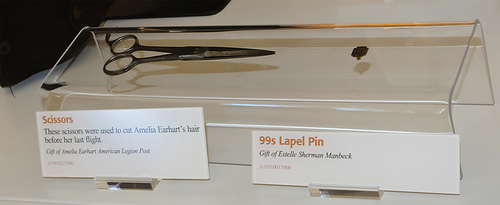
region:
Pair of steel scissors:
[90, 25, 306, 93]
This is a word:
[39, 112, 79, 127]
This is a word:
[37, 125, 61, 137]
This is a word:
[58, 124, 85, 136]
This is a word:
[81, 124, 102, 136]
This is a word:
[277, 132, 307, 147]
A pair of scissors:
[105, 33, 269, 78]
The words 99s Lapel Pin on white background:
[254, 130, 334, 152]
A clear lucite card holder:
[89, 171, 168, 190]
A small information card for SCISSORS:
[39, 103, 207, 180]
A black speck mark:
[342, 38, 376, 69]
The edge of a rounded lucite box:
[414, 13, 495, 173]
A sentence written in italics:
[40, 145, 157, 158]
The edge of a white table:
[1, 180, 54, 204]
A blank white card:
[378, 128, 461, 199]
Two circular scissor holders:
[108, 27, 137, 82]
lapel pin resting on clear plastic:
[345, 42, 372, 67]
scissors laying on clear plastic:
[100, 28, 277, 78]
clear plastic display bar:
[35, 18, 495, 183]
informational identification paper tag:
[243, 122, 466, 202]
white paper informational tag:
[31, 100, 216, 187]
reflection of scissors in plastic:
[104, 46, 282, 93]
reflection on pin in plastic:
[352, 59, 371, 76]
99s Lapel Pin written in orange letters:
[257, 133, 324, 150]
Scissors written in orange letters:
[40, 112, 75, 124]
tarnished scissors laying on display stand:
[99, 25, 279, 80]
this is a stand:
[47, 23, 465, 185]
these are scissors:
[84, 25, 258, 95]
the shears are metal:
[84, 41, 245, 73]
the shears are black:
[98, 37, 216, 92]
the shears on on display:
[95, 13, 280, 94]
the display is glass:
[50, 74, 311, 151]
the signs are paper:
[41, 108, 278, 198]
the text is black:
[60, 110, 178, 152]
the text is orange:
[27, 103, 74, 121]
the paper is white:
[35, 101, 155, 176]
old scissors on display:
[97, 28, 291, 83]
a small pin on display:
[345, 35, 380, 69]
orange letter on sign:
[41, 114, 49, 125]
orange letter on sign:
[46, 116, 53, 125]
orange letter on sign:
[51, 114, 58, 125]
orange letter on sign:
[277, 133, 284, 145]